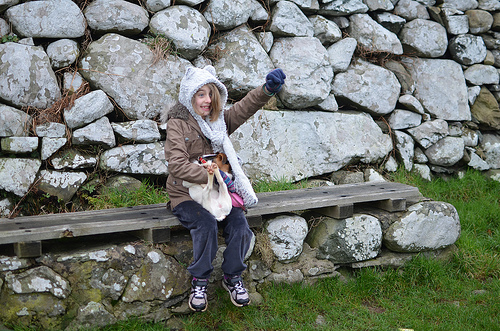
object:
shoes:
[188, 276, 210, 312]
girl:
[159, 64, 269, 313]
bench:
[101, 181, 419, 244]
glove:
[265, 68, 287, 94]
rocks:
[6, 0, 85, 38]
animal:
[180, 159, 234, 223]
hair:
[207, 83, 222, 122]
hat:
[180, 63, 229, 123]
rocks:
[385, 200, 462, 254]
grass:
[401, 258, 431, 284]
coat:
[161, 89, 273, 210]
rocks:
[410, 57, 473, 121]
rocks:
[72, 116, 118, 146]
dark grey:
[135, 151, 159, 169]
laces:
[194, 285, 205, 298]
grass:
[43, 106, 63, 119]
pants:
[176, 201, 255, 286]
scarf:
[187, 111, 261, 210]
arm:
[225, 85, 270, 133]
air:
[238, 40, 326, 69]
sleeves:
[161, 121, 209, 187]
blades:
[144, 176, 151, 184]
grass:
[136, 192, 156, 205]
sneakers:
[222, 276, 252, 307]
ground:
[350, 272, 496, 314]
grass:
[153, 38, 174, 56]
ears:
[185, 67, 196, 80]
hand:
[265, 69, 286, 93]